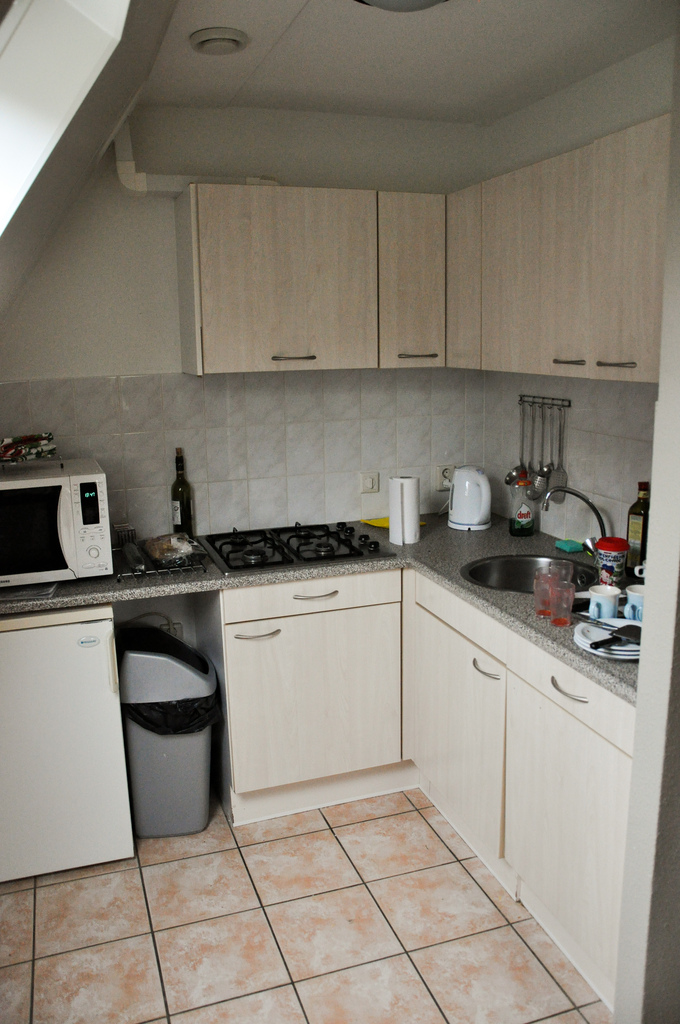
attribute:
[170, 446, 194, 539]
bottle — green, wine, corked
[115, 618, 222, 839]
trash can — grey, gray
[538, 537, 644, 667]
dishes — dirty, piled, cluttered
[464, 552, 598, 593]
sink — chrome, round, silver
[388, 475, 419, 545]
paper towels — white, rolled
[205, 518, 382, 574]
range — gas, cooktop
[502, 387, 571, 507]
utinsils — for cooking, hanging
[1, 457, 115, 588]
microwave — white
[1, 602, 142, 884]
refrigerator — small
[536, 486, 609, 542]
faucet — chrome, silver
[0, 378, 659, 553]
backsplash — white, tiled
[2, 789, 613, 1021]
floor — orange, tiled, white, peach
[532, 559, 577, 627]
glasses — empty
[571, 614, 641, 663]
plates — stacked, empty, round, white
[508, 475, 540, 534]
dish soap — empty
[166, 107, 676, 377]
cabinets — white, wood grain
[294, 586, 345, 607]
handle — silver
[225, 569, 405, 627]
drawer — white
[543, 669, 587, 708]
handle — silver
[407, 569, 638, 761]
drawer — white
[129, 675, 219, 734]
bag — black